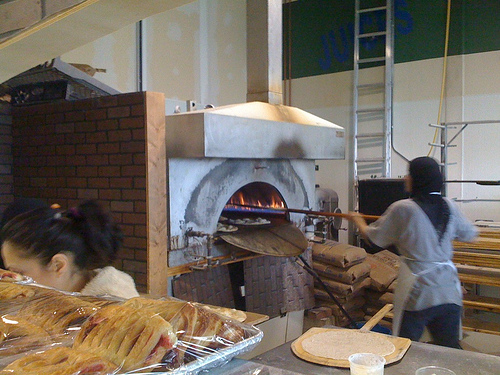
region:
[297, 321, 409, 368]
Pie dough on tray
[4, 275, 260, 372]
Pastries wrapped to stay fresh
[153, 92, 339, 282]
Large pizza pie oven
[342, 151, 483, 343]
Woman putting pizza in oven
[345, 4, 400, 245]
Ladder against a wall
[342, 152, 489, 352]
Woman in grey shirt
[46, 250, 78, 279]
Womans ear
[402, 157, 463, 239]
Black hair on woman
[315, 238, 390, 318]
Bags of flower in the background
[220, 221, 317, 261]
Door to pie oven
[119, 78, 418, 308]
a stone oven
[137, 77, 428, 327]
a stone oven for pizza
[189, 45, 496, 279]
a woman placing pizza in oven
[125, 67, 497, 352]
a woman placing pizza in ston eoven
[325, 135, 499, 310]
a woman wearing an apron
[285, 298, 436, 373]
pizza dough on board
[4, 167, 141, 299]
a woman with hair up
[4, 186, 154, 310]
a woman with hair in pony tail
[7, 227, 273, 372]
a tray of pastries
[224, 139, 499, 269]
a woman holding a long spatula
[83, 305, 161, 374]
raspberry danish on left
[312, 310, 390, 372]
wooden baking paddle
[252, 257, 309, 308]
red brick under oven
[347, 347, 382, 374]
plastic cup with batter inside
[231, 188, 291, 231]
red open fire in oven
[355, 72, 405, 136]
silver tall ladder against wall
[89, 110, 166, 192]
red brick wall on left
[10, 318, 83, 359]
pastry covered with plastic wrap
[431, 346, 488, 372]
grey countertop on ride side of photo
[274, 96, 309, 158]
burn mark on oven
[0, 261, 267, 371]
Freshly made berry filled strudels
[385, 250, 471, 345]
White full length apron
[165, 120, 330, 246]
Brick fire oven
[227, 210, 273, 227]
Oven fire baked pizza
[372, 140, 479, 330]
Cook in the restaurant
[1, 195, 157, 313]
Assistant front counter worker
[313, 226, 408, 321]
Large unopened bags of flour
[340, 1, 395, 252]
Tall metal ladder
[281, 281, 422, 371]
Wooden spatula for pizza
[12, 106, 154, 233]
Brick design surrounding the oven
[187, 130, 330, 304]
pizza brick oven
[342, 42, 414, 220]
ladder against the wall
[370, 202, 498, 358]
woman is wearing an apron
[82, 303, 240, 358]
danishes on a tray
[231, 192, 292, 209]
fire in the oven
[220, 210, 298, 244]
pizzas in the oven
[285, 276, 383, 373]
board to put pizza in the oven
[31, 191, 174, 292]
woman has her hair in a ponytail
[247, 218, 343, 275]
pizza oven door open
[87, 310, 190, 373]
cherry danishes